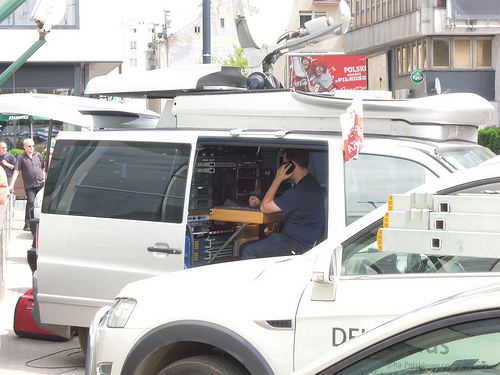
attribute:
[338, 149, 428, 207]
window — glass 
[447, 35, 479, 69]
window — glassy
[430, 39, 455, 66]
window — glassy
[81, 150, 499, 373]
car — white 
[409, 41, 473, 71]
window — glassy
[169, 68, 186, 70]
isaldn — white 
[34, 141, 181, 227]
window — glass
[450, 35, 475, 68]
window — glassy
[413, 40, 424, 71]
glass window — glassy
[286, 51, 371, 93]
sign — red , white , black 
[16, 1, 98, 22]
window — glassy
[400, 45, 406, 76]
window — glassy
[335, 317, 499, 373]
window — glass 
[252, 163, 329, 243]
shirt — blue 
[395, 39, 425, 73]
window — glassy